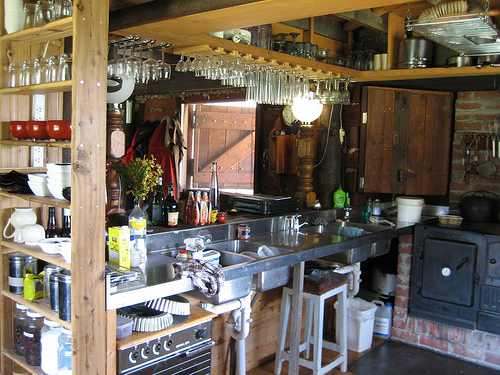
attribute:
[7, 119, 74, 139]
dishes — small, red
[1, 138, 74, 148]
shelf — wooden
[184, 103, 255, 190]
window — wooden, open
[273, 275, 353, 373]
stool — brown, white, wooden, padded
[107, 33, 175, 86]
glasses — hanging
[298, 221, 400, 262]
sink — stainless sink, silver, metal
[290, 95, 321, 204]
lamp — wooden, turned on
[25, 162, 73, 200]
dishes — white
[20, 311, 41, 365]
jar — glass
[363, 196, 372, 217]
soap dispenser — green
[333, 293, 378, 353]
trashcan — white, plastic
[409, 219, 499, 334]
oven — cast iron, wood fired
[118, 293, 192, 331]
pans — silver, fluted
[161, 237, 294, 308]
sinks — stainless steel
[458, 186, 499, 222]
pot — cast iron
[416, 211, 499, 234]
stove — wood burning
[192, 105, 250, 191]
door — open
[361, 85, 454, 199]
cupboard door — wooden